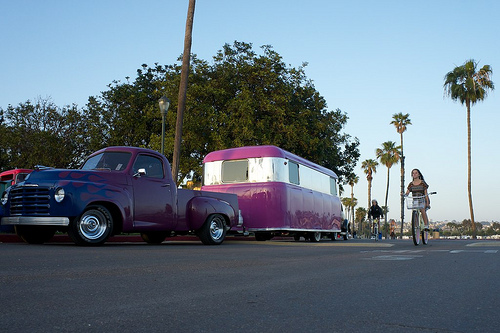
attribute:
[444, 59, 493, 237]
palm tree — tall, thin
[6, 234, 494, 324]
street — paved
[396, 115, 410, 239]
palm tree — tall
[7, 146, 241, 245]
truck — maroon, older, classic, brown, purple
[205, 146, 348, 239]
purple trailer — classic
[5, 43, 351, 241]
trees — green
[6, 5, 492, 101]
sky — blue, clear, cloudy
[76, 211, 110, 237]
rim — chrome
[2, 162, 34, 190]
truck cab — red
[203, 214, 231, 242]
tire — round, black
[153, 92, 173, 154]
lamp post — tall, green, metal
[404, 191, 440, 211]
basket — wire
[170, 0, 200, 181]
pole — tall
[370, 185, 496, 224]
clouds — white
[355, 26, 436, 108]
clouds — white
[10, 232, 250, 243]
curb — red